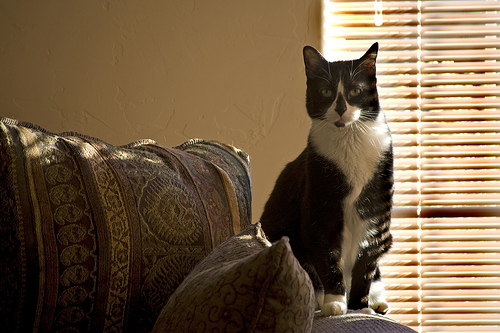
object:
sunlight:
[320, 0, 360, 49]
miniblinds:
[320, 0, 497, 333]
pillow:
[150, 222, 312, 332]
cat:
[254, 37, 400, 319]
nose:
[334, 100, 348, 116]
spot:
[334, 80, 346, 101]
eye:
[320, 86, 333, 98]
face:
[309, 69, 382, 121]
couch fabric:
[0, 181, 142, 328]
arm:
[348, 258, 391, 314]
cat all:
[5, 41, 399, 332]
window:
[318, 0, 496, 333]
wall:
[0, 0, 324, 221]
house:
[1, 0, 498, 330]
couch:
[0, 116, 415, 331]